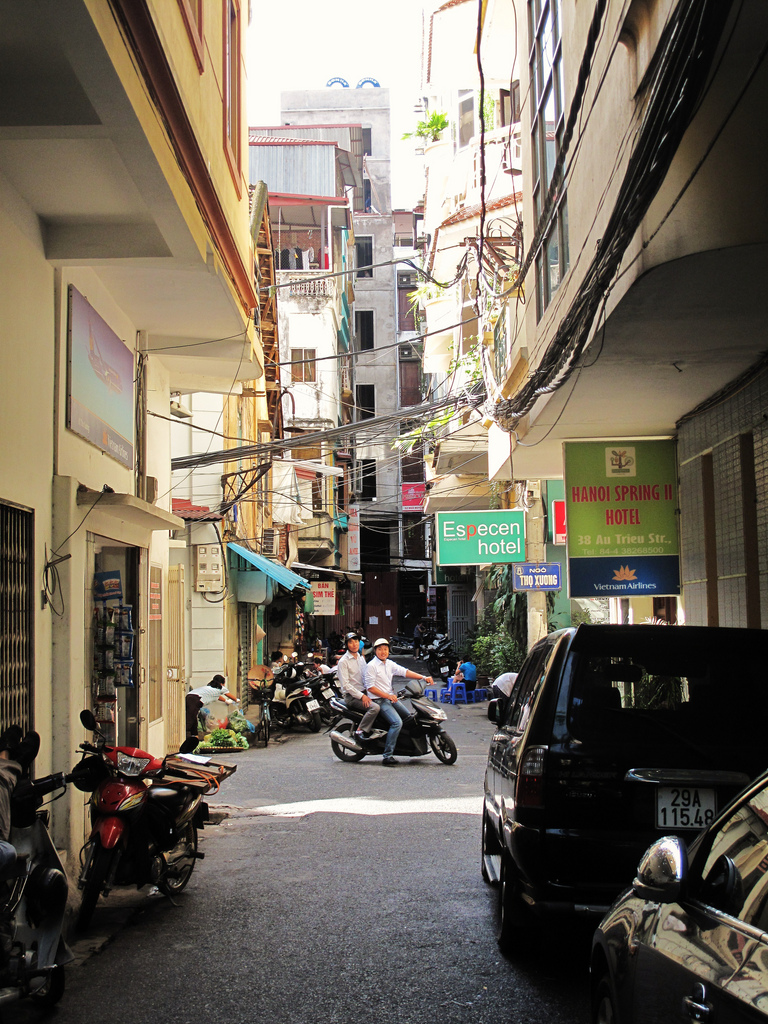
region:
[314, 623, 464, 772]
Two men on a motorcycle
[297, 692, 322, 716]
License plate on the motorcycle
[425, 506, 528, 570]
Sign on the building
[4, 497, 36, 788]
metal bars on the door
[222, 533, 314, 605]
awning over the building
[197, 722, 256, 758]
vegetables on the skid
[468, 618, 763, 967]
Car on the raod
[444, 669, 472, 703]
Blue chair by the building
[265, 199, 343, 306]
balcony on the building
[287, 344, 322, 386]
window in the building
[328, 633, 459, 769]
the men on the moped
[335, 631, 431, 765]
the men are wearing helmets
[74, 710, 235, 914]
the moped is red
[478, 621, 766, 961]
the car is parked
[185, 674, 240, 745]
the woman is bending over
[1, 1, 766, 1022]
the narrow road between the buildings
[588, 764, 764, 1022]
the black car is parked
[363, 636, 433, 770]
the man is wearing blue jeans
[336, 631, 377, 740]
the man is wearing gray pants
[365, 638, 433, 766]
the man wearing a long sleeved shirt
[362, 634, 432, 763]
Man wearing a white button down shirt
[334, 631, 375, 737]
Man riding a motorcycle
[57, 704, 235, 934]
Red motorcycle parked next to a building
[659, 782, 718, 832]
Black and white license plate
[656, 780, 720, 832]
License plate on the black car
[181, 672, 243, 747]
Woman wearing black pants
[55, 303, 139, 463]
A sign on a building.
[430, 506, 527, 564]
A sign on a building.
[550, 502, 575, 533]
A sign on a building.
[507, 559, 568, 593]
A sign on a building.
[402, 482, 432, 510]
A sign on a building.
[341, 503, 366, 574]
A sign on a building.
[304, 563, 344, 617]
A sign on a building.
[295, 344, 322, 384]
A window on a building.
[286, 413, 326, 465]
A window on a building.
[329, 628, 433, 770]
two men riding motorcycles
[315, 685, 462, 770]
motorcycle on road is black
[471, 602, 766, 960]
small suv is parked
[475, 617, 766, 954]
small suv is black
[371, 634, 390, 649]
man wearing white helmet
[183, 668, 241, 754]
woman leaning over vegetables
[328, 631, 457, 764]
Two Asian men on a motorbike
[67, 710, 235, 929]
Red motorbike parked on the street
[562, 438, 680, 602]
Hanoit Spring II Hotel sign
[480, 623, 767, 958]
Dark colored van parked on the street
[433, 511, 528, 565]
Red, green, and white Especen Hotel sign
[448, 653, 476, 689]
Woman in a blue top and black skirt sitting down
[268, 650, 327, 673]
People sitting outside a restaurant in Vietnam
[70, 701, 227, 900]
a moped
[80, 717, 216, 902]
the moped is red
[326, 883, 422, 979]
the ground is grey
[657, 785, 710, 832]
a license plate on the van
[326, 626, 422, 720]
two people on the moped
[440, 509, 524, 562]
a sign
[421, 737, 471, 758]
front tire on the moped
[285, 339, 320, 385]
a small window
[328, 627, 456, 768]
men on motor bike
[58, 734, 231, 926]
motorcycle is red on street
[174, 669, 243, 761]
woman on street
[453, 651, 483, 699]
woman wearing blue shirt